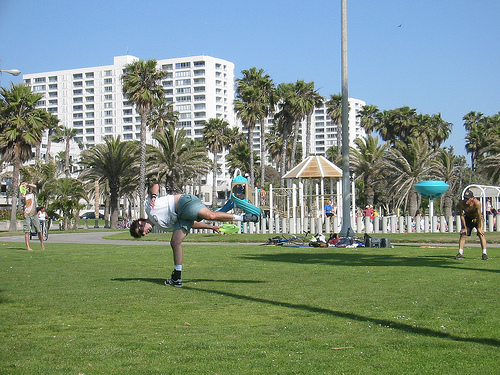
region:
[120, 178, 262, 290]
Man doing a roundhouse kick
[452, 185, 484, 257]
Man bending over with hands on knees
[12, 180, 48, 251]
Man throwing frisbee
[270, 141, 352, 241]
Gazebo in the background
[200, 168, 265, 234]
Playground in the background with slide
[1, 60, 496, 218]
Palm trees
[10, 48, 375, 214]
Large white hotels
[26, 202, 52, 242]
Woman riding bicycle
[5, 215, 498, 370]
Flat, grassy area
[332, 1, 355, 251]
Extremely tall pole in the field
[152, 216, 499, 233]
a small white wooden fence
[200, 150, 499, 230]
A large playground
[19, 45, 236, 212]
A large white building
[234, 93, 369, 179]
A large white building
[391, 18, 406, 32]
a bird in the sky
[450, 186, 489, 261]
a man in a black hat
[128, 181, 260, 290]
a man in a white shirt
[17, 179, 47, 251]
a man in a brown shirt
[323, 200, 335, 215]
a person in a blue shirt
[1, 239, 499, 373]
a grassy field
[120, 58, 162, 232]
a tall and green palm tree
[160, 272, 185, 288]
black and white men's sports shoe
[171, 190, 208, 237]
green shorts on man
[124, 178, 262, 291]
man in green shorts exercising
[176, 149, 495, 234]
a children's playground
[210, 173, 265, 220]
a green slide in children's playground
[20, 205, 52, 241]
woman in white shirt riding a bike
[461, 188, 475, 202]
black baseball cap with red print on it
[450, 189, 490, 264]
guy wearing baseball cap standing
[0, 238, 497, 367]
green grassy field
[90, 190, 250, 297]
a man in ground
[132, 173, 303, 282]
a man doing yoga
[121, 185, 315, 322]
a man bending down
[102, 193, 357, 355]
a man standing in ground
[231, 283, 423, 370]
shadow on the ground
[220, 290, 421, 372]
shadow of the man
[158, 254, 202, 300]
shoe of the person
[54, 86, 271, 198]
a group of trees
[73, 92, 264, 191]
large trees on the back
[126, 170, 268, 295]
man holds a Frisbee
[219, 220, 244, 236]
Frisbee is color green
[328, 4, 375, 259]
a pole in a park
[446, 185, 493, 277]
man is in green field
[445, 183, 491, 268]
man is bent forward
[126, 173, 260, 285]
man is bent on side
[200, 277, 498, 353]
a shadow on grass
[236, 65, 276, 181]
a palm green tree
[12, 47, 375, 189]
white buildings behind palms